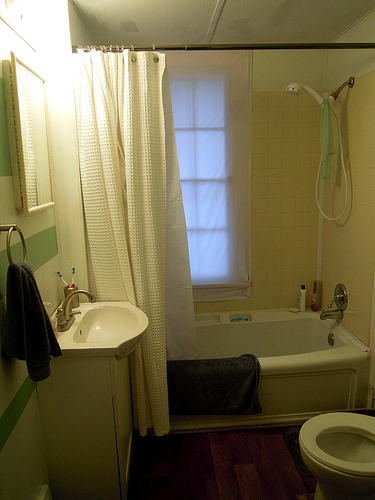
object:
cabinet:
[0, 52, 56, 218]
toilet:
[298, 410, 374, 497]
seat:
[300, 411, 375, 475]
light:
[0, 0, 88, 109]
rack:
[6, 225, 28, 267]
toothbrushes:
[56, 270, 71, 289]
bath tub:
[170, 307, 371, 433]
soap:
[288, 306, 299, 313]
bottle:
[299, 284, 307, 311]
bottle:
[311, 279, 320, 311]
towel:
[5, 260, 63, 384]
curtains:
[164, 57, 253, 305]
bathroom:
[0, 1, 373, 497]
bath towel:
[166, 353, 263, 416]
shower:
[285, 76, 355, 221]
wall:
[0, 1, 74, 498]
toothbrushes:
[71, 265, 76, 287]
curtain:
[70, 49, 171, 440]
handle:
[231, 318, 246, 322]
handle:
[302, 84, 322, 105]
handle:
[60, 277, 69, 289]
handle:
[71, 273, 74, 287]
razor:
[230, 316, 251, 322]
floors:
[127, 426, 306, 500]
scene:
[0, 0, 373, 500]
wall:
[175, 56, 328, 311]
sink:
[72, 301, 150, 347]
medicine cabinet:
[1, 47, 54, 216]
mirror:
[15, 61, 51, 211]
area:
[0, 0, 375, 500]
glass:
[64, 286, 79, 307]